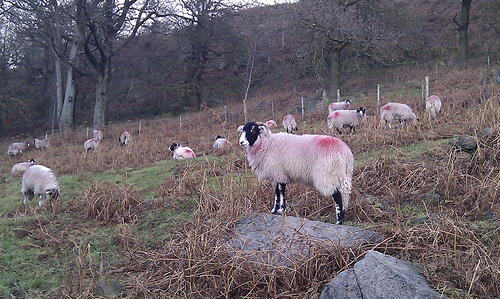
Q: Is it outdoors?
A: Yes, it is outdoors.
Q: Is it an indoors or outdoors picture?
A: It is outdoors.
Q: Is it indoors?
A: No, it is outdoors.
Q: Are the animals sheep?
A: Yes, all the animals are sheep.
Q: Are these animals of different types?
A: No, all the animals are sheep.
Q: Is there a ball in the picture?
A: No, there are no balls.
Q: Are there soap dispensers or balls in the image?
A: No, there are no balls or soap dispensers.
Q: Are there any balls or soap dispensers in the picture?
A: No, there are no balls or soap dispensers.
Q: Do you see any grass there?
A: Yes, there is grass.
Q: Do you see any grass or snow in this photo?
A: Yes, there is grass.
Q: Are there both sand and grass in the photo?
A: No, there is grass but no sand.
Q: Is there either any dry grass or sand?
A: Yes, there is dry grass.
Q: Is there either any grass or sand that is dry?
A: Yes, the grass is dry.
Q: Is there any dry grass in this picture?
A: Yes, there is dry grass.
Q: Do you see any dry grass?
A: Yes, there is dry grass.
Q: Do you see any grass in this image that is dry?
A: Yes, there is grass that is dry.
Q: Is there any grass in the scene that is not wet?
A: Yes, there is dry grass.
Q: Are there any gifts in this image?
A: No, there are no gifts.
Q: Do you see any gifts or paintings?
A: No, there are no gifts or paintings.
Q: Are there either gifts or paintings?
A: No, there are no gifts or paintings.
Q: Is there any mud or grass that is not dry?
A: No, there is grass but it is dry.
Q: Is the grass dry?
A: Yes, the grass is dry.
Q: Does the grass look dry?
A: Yes, the grass is dry.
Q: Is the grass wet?
A: No, the grass is dry.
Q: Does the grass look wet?
A: No, the grass is dry.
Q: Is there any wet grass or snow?
A: No, there is grass but it is dry.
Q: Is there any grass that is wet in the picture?
A: No, there is grass but it is dry.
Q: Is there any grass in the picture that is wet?
A: No, there is grass but it is dry.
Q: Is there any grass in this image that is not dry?
A: No, there is grass but it is dry.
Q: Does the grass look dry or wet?
A: The grass is dry.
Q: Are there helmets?
A: No, there are no helmets.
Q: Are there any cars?
A: No, there are no cars.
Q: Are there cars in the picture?
A: No, there are no cars.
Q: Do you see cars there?
A: No, there are no cars.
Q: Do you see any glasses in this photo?
A: No, there are no glasses.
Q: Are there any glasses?
A: No, there are no glasses.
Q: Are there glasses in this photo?
A: No, there are no glasses.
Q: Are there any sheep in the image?
A: Yes, there is a sheep.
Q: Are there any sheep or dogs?
A: Yes, there is a sheep.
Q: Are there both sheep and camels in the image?
A: No, there is a sheep but no camels.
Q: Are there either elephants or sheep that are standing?
A: Yes, the sheep is standing.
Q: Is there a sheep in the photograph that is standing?
A: Yes, there is a sheep that is standing.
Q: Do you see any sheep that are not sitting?
A: Yes, there is a sheep that is standing .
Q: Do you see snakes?
A: No, there are no snakes.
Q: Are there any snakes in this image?
A: No, there are no snakes.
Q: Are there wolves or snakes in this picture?
A: No, there are no snakes or wolves.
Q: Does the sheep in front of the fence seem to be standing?
A: Yes, the sheep is standing.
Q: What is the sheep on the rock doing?
A: The sheep is standing.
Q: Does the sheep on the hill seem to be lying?
A: No, the sheep is standing.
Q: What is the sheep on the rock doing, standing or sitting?
A: The sheep is standing.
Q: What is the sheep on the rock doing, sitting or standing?
A: The sheep is standing.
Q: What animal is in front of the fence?
A: The sheep is in front of the fence.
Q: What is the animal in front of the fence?
A: The animal is a sheep.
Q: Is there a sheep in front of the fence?
A: Yes, there is a sheep in front of the fence.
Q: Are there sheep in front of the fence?
A: Yes, there is a sheep in front of the fence.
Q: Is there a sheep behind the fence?
A: No, the sheep is in front of the fence.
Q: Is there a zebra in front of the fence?
A: No, there is a sheep in front of the fence.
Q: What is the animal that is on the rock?
A: The animal is a sheep.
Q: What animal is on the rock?
A: The animal is a sheep.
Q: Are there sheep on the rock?
A: Yes, there is a sheep on the rock.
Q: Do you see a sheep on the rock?
A: Yes, there is a sheep on the rock.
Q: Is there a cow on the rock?
A: No, there is a sheep on the rock.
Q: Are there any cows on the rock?
A: No, there is a sheep on the rock.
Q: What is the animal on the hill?
A: The animal is a sheep.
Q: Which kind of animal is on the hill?
A: The animal is a sheep.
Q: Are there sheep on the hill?
A: Yes, there is a sheep on the hill.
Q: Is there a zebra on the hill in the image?
A: No, there is a sheep on the hill.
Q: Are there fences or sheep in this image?
A: Yes, there is a sheep.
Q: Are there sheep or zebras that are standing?
A: Yes, the sheep is standing.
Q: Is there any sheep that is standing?
A: Yes, there is a sheep that is standing.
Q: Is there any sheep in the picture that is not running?
A: Yes, there is a sheep that is standing.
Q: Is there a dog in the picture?
A: No, there are no dogs.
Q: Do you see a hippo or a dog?
A: No, there are no dogs or hippos.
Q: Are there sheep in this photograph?
A: Yes, there is a sheep.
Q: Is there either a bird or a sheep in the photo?
A: Yes, there is a sheep.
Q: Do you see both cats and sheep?
A: No, there is a sheep but no cats.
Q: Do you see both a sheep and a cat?
A: No, there is a sheep but no cats.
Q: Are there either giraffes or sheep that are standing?
A: Yes, the sheep is standing.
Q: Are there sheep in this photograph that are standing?
A: Yes, there is a sheep that is standing.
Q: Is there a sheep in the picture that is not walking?
A: Yes, there is a sheep that is standing.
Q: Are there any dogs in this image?
A: No, there are no dogs.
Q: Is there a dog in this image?
A: No, there are no dogs.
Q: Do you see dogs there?
A: No, there are no dogs.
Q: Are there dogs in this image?
A: No, there are no dogs.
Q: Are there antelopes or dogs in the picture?
A: No, there are no dogs or antelopes.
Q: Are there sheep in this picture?
A: Yes, there is a sheep.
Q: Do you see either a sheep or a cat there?
A: Yes, there is a sheep.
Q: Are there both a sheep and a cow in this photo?
A: No, there is a sheep but no cows.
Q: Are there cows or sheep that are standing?
A: Yes, the sheep is standing.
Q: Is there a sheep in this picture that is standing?
A: Yes, there is a sheep that is standing.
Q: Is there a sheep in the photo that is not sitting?
A: Yes, there is a sheep that is standing.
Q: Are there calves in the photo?
A: No, there are no calves.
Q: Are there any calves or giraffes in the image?
A: No, there are no calves or giraffes.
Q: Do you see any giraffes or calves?
A: No, there are no calves or giraffes.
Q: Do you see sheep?
A: Yes, there is a sheep.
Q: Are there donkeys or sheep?
A: Yes, there is a sheep.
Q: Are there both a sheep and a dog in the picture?
A: No, there is a sheep but no dogs.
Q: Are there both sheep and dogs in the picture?
A: No, there is a sheep but no dogs.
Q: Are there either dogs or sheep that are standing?
A: Yes, the sheep is standing.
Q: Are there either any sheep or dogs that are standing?
A: Yes, the sheep is standing.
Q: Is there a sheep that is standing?
A: Yes, there is a sheep that is standing.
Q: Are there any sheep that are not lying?
A: Yes, there is a sheep that is standing.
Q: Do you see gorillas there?
A: No, there are no gorillas.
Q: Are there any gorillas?
A: No, there are no gorillas.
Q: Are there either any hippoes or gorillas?
A: No, there are no gorillas or hippoes.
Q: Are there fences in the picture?
A: Yes, there is a fence.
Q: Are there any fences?
A: Yes, there is a fence.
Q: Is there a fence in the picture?
A: Yes, there is a fence.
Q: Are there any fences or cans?
A: Yes, there is a fence.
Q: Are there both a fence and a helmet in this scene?
A: No, there is a fence but no helmets.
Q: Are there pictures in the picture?
A: No, there are no pictures.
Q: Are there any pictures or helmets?
A: No, there are no pictures or helmets.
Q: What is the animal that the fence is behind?
A: The animal is a sheep.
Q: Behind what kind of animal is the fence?
A: The fence is behind the sheep.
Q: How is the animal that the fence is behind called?
A: The animal is a sheep.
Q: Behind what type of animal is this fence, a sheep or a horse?
A: The fence is behind a sheep.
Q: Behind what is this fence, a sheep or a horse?
A: The fence is behind a sheep.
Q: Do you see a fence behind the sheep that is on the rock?
A: Yes, there is a fence behind the sheep.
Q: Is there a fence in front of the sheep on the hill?
A: No, the fence is behind the sheep.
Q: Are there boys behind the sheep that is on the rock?
A: No, there is a fence behind the sheep.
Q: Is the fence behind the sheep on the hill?
A: Yes, the fence is behind the sheep.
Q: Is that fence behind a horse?
A: No, the fence is behind the sheep.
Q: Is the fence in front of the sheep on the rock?
A: No, the fence is behind the sheep.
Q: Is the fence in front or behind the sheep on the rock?
A: The fence is behind the sheep.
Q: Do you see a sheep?
A: Yes, there is a sheep.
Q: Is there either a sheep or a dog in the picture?
A: Yes, there is a sheep.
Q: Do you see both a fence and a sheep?
A: Yes, there are both a sheep and a fence.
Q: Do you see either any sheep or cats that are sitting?
A: Yes, the sheep is sitting.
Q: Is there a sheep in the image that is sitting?
A: Yes, there is a sheep that is sitting.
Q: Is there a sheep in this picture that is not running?
A: Yes, there is a sheep that is sitting.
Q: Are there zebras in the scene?
A: No, there are no zebras.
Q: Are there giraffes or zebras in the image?
A: No, there are no zebras or giraffes.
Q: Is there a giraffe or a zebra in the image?
A: No, there are no zebras or giraffes.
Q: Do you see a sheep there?
A: Yes, there is a sheep.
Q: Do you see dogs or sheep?
A: Yes, there is a sheep.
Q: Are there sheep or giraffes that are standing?
A: Yes, the sheep is standing.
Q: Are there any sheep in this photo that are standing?
A: Yes, there is a sheep that is standing.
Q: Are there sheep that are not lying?
A: Yes, there is a sheep that is standing.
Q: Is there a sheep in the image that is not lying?
A: Yes, there is a sheep that is standing.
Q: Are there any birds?
A: No, there are no birds.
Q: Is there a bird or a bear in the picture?
A: No, there are no birds or bears.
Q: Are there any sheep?
A: Yes, there is a sheep.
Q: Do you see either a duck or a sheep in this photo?
A: Yes, there is a sheep.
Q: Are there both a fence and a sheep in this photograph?
A: Yes, there are both a sheep and a fence.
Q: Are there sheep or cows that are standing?
A: Yes, the sheep is standing.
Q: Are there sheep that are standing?
A: Yes, there is a sheep that is standing.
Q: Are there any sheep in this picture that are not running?
A: Yes, there is a sheep that is standing.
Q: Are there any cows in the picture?
A: No, there are no cows.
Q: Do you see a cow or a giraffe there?
A: No, there are no cows or giraffes.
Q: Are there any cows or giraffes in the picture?
A: No, there are no cows or giraffes.